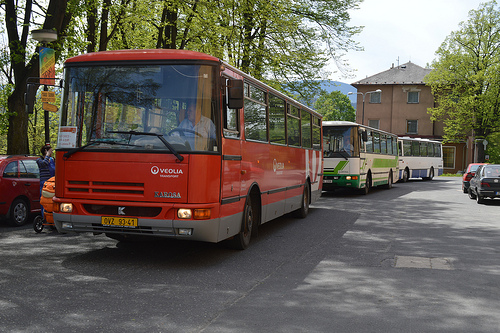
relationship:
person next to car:
[37, 141, 50, 186] [3, 154, 50, 220]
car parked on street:
[471, 164, 498, 199] [19, 121, 491, 320]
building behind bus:
[354, 58, 464, 168] [392, 136, 441, 180]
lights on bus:
[176, 206, 213, 223] [54, 46, 324, 266]